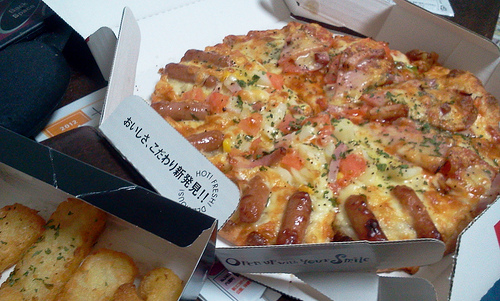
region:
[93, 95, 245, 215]
a text in the box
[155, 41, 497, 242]
a round pizza in box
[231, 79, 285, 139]
black marks on the pizza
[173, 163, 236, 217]
a round in the box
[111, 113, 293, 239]
a label in the pizza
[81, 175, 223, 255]
top part of the box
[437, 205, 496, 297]
a part of white box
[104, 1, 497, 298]
sliced pizza in box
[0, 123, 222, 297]
fried potatoes in box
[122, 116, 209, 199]
asian characters on box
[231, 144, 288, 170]
slice of onion on pizza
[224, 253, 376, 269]
english words on box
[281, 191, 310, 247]
sausage link on pizaa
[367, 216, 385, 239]
burn mark on link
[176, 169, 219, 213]
words arranged in a circle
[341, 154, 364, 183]
piece of tomato on pizza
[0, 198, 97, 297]
a box of garlic bread sticks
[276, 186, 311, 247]
a hotdog on a pizza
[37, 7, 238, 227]
a cardboard food container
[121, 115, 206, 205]
a warning written in a foreign language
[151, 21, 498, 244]
a pizza in a cardboard pizza box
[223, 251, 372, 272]
the business brand name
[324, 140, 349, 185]
a piece of ham on the pizza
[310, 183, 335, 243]
a chunk of mozzarella cheese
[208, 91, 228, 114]
a tomato slice on the pizza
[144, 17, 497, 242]
hot dogs on the pizza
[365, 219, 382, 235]
brown spot on the hot dog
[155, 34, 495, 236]
green herbs on the pizza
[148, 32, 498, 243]
the pizza is greasy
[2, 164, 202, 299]
garlic sticks in the box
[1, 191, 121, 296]
green herbs on the sticks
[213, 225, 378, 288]
black letters on box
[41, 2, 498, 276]
pizza in a cardboard box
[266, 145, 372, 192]
red tomatoes on the pizza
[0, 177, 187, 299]
sticks are rectangular shaped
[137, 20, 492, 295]
pizza kept in the box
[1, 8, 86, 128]
bag kept near the pizza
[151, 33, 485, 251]
brown and cream color pizza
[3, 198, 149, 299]
some other eatables in the box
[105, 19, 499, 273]
pizza kept in a table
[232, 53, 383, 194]
onion and potato toppings of pizza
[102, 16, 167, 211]
white color cardboard box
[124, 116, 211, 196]
text written in black color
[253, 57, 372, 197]
cheese in the pizza toppings